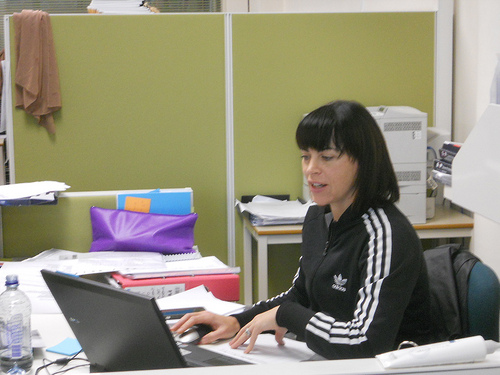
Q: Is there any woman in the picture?
A: Yes, there is a woman.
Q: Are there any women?
A: Yes, there is a woman.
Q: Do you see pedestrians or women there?
A: Yes, there is a woman.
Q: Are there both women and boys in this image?
A: No, there is a woman but no boys.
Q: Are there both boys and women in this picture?
A: No, there is a woman but no boys.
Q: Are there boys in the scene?
A: No, there are no boys.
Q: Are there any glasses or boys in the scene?
A: No, there are no boys or glasses.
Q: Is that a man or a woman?
A: That is a woman.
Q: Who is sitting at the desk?
A: The woman is sitting at the desk.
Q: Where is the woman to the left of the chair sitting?
A: The woman is sitting at the desk.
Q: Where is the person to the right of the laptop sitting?
A: The woman is sitting at the desk.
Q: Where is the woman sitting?
A: The woman is sitting at the desk.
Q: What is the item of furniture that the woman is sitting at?
A: The piece of furniture is a desk.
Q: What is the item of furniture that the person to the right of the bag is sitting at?
A: The piece of furniture is a desk.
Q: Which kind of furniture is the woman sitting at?
A: The woman is sitting at the desk.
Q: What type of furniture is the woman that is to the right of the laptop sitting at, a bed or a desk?
A: The woman is sitting at a desk.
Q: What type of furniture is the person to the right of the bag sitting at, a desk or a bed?
A: The woman is sitting at a desk.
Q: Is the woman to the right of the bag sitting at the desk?
A: Yes, the woman is sitting at the desk.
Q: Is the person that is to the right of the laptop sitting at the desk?
A: Yes, the woman is sitting at the desk.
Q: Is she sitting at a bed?
A: No, the woman is sitting at the desk.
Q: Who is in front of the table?
A: The woman is in front of the table.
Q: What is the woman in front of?
A: The woman is in front of the table.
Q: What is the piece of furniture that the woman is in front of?
A: The piece of furniture is a table.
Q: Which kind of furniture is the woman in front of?
A: The woman is in front of the table.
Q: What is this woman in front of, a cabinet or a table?
A: The woman is in front of a table.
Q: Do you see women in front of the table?
A: Yes, there is a woman in front of the table.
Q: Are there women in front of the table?
A: Yes, there is a woman in front of the table.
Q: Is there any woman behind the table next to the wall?
A: No, the woman is in front of the table.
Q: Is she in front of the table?
A: Yes, the woman is in front of the table.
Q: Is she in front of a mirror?
A: No, the woman is in front of the table.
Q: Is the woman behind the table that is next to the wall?
A: No, the woman is in front of the table.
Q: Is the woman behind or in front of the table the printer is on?
A: The woman is in front of the table.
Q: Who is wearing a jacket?
A: The woman is wearing a jacket.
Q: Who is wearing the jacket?
A: The woman is wearing a jacket.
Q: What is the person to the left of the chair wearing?
A: The woman is wearing a jacket.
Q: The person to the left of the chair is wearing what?
A: The woman is wearing a jacket.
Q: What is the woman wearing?
A: The woman is wearing a jacket.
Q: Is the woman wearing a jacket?
A: Yes, the woman is wearing a jacket.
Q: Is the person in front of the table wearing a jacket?
A: Yes, the woman is wearing a jacket.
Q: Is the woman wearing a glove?
A: No, the woman is wearing a jacket.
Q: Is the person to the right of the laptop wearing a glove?
A: No, the woman is wearing a jacket.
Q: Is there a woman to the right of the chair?
A: No, the woman is to the left of the chair.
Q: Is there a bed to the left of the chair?
A: No, there is a woman to the left of the chair.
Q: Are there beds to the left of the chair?
A: No, there is a woman to the left of the chair.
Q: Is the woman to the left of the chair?
A: Yes, the woman is to the left of the chair.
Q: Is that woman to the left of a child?
A: No, the woman is to the left of the chair.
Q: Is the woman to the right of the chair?
A: No, the woman is to the left of the chair.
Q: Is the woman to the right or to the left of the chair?
A: The woman is to the left of the chair.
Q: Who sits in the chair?
A: The woman sits in the chair.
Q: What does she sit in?
A: The woman sits in the chair.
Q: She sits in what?
A: The woman sits in the chair.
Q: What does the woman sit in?
A: The woman sits in the chair.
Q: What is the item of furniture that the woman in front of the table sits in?
A: The piece of furniture is a chair.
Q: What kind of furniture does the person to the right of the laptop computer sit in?
A: The woman sits in the chair.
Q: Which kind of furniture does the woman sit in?
A: The woman sits in the chair.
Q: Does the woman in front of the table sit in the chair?
A: Yes, the woman sits in the chair.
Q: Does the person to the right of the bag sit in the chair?
A: Yes, the woman sits in the chair.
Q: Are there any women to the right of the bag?
A: Yes, there is a woman to the right of the bag.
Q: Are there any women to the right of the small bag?
A: Yes, there is a woman to the right of the bag.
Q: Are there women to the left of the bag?
A: No, the woman is to the right of the bag.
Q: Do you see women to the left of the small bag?
A: No, the woman is to the right of the bag.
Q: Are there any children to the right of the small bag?
A: No, there is a woman to the right of the bag.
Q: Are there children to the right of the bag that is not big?
A: No, there is a woman to the right of the bag.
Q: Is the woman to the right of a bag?
A: Yes, the woman is to the right of a bag.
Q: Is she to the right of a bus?
A: No, the woman is to the right of a bag.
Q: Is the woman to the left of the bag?
A: No, the woman is to the right of the bag.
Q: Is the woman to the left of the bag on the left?
A: No, the woman is to the right of the bag.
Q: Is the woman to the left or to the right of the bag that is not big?
A: The woman is to the right of the bag.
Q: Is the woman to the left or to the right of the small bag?
A: The woman is to the right of the bag.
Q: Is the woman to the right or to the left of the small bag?
A: The woman is to the right of the bag.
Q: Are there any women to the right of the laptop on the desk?
A: Yes, there is a woman to the right of the laptop.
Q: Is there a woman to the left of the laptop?
A: No, the woman is to the right of the laptop.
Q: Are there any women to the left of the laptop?
A: No, the woman is to the right of the laptop.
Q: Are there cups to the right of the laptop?
A: No, there is a woman to the right of the laptop.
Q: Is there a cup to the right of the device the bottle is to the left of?
A: No, there is a woman to the right of the laptop.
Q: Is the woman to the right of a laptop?
A: Yes, the woman is to the right of a laptop.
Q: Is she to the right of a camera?
A: No, the woman is to the right of a laptop.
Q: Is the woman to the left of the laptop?
A: No, the woman is to the right of the laptop.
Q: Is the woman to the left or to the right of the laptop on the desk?
A: The woman is to the right of the laptop.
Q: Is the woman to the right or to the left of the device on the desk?
A: The woman is to the right of the laptop.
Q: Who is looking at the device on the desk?
A: The woman is looking at the laptop.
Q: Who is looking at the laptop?
A: The woman is looking at the laptop.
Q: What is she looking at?
A: The woman is looking at the laptop.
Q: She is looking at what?
A: The woman is looking at the laptop.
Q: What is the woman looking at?
A: The woman is looking at the laptop.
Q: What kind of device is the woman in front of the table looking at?
A: The woman is looking at the laptop.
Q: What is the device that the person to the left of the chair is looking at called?
A: The device is a laptop.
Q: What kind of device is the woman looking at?
A: The woman is looking at the laptop.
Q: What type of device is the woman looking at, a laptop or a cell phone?
A: The woman is looking at a laptop.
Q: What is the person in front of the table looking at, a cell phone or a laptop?
A: The woman is looking at a laptop.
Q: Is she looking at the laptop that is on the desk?
A: Yes, the woman is looking at the laptop.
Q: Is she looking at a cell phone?
A: No, the woman is looking at the laptop.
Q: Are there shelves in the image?
A: No, there are no shelves.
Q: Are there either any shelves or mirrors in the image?
A: No, there are no shelves or mirrors.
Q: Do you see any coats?
A: Yes, there is a coat.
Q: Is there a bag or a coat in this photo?
A: Yes, there is a coat.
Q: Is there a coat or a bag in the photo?
A: Yes, there is a coat.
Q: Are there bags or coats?
A: Yes, there is a coat.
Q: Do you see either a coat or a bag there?
A: Yes, there is a coat.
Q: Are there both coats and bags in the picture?
A: Yes, there are both a coat and a bag.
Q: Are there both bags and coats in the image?
A: Yes, there are both a coat and a bag.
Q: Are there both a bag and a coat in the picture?
A: Yes, there are both a coat and a bag.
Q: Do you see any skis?
A: No, there are no skis.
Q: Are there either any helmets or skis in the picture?
A: No, there are no skis or helmets.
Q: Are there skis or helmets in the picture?
A: No, there are no skis or helmets.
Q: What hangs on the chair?
A: The coat hangs on the chair.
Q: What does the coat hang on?
A: The coat hangs on the chair.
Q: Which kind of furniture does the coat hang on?
A: The coat hangs on the chair.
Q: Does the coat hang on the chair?
A: Yes, the coat hangs on the chair.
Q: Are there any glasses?
A: No, there are no glasses.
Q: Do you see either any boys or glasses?
A: No, there are no glasses or boys.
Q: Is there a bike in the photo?
A: No, there are no bikes.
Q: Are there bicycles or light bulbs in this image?
A: No, there are no bicycles or light bulbs.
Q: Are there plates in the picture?
A: No, there are no plates.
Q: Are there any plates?
A: No, there are no plates.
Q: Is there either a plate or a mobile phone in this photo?
A: No, there are no plates or cell phones.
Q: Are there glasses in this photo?
A: No, there are no glasses.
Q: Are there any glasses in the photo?
A: No, there are no glasses.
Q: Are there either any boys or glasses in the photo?
A: No, there are no glasses or boys.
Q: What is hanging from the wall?
A: The sweater is hanging from the wall.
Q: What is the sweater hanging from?
A: The sweater is hanging from the wall.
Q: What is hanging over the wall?
A: The sweater is hanging over the wall.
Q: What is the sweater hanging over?
A: The sweater is hanging over the wall.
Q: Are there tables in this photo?
A: Yes, there is a table.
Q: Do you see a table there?
A: Yes, there is a table.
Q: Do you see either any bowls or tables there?
A: Yes, there is a table.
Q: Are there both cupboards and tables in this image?
A: No, there is a table but no cupboards.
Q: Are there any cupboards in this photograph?
A: No, there are no cupboards.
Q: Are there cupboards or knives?
A: No, there are no cupboards or knives.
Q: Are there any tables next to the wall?
A: Yes, there is a table next to the wall.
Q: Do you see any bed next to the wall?
A: No, there is a table next to the wall.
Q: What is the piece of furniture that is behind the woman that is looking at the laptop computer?
A: The piece of furniture is a table.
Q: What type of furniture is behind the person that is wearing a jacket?
A: The piece of furniture is a table.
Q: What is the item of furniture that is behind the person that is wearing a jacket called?
A: The piece of furniture is a table.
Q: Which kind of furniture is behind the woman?
A: The piece of furniture is a table.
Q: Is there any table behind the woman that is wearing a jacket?
A: Yes, there is a table behind the woman.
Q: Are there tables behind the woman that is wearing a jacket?
A: Yes, there is a table behind the woman.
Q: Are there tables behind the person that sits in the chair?
A: Yes, there is a table behind the woman.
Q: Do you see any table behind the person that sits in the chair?
A: Yes, there is a table behind the woman.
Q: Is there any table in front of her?
A: No, the table is behind the woman.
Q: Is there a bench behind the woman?
A: No, there is a table behind the woman.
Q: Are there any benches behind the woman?
A: No, there is a table behind the woman.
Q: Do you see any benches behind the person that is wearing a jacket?
A: No, there is a table behind the woman.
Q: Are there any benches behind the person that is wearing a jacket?
A: No, there is a table behind the woman.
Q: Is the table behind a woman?
A: Yes, the table is behind a woman.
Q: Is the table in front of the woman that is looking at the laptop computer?
A: No, the table is behind the woman.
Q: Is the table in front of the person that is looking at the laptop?
A: No, the table is behind the woman.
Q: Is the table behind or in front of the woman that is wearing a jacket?
A: The table is behind the woman.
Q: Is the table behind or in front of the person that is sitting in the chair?
A: The table is behind the woman.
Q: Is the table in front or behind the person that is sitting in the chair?
A: The table is behind the woman.